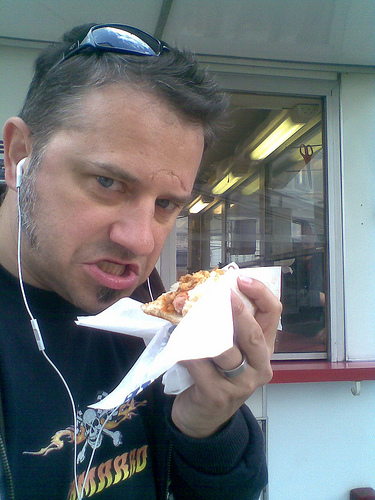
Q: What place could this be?
A: It is a shop.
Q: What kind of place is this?
A: It is a shop.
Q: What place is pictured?
A: It is a shop.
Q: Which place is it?
A: It is a shop.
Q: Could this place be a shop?
A: Yes, it is a shop.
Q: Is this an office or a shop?
A: It is a shop.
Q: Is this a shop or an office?
A: It is a shop.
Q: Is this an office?
A: No, it is a shop.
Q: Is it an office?
A: No, it is a shop.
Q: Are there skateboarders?
A: No, there are no skateboarders.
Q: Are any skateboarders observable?
A: No, there are no skateboarders.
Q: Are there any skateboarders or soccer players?
A: No, there are no skateboarders or soccer players.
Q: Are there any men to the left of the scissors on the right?
A: Yes, there is a man to the left of the scissors.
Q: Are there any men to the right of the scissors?
A: No, the man is to the left of the scissors.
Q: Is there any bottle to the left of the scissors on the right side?
A: No, there is a man to the left of the scissors.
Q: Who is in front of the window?
A: The man is in front of the window.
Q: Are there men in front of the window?
A: Yes, there is a man in front of the window.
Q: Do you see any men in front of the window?
A: Yes, there is a man in front of the window.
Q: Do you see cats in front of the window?
A: No, there is a man in front of the window.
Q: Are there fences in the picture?
A: No, there are no fences.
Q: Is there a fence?
A: No, there are no fences.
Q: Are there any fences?
A: No, there are no fences.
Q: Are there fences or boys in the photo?
A: No, there are no fences or boys.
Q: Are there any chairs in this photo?
A: No, there are no chairs.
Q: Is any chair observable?
A: No, there are no chairs.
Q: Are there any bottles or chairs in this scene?
A: No, there are no chairs or bottles.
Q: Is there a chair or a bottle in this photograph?
A: No, there are no chairs or bottles.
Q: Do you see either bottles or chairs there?
A: No, there are no chairs or bottles.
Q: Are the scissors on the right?
A: Yes, the scissors are on the right of the image.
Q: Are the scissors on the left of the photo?
A: No, the scissors are on the right of the image.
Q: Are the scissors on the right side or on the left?
A: The scissors are on the right of the image.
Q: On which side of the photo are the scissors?
A: The scissors are on the right of the image.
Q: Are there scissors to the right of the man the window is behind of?
A: Yes, there are scissors to the right of the man.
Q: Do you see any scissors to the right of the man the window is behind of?
A: Yes, there are scissors to the right of the man.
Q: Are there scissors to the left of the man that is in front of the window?
A: No, the scissors are to the right of the man.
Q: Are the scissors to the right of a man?
A: Yes, the scissors are to the right of a man.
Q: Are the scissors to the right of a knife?
A: No, the scissors are to the right of a man.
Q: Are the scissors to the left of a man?
A: No, the scissors are to the right of a man.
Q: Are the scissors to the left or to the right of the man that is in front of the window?
A: The scissors are to the right of the man.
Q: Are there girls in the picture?
A: No, there are no girls.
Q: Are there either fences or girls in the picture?
A: No, there are no girls or fences.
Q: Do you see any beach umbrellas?
A: No, there are no beach umbrellas.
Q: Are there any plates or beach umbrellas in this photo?
A: No, there are no beach umbrellas or plates.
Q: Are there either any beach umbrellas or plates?
A: No, there are no beach umbrellas or plates.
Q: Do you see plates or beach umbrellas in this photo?
A: No, there are no beach umbrellas or plates.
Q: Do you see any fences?
A: No, there are no fences.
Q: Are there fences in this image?
A: No, there are no fences.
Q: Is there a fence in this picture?
A: No, there are no fences.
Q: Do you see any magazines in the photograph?
A: No, there are no magazines.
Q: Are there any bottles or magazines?
A: No, there are no magazines or bottles.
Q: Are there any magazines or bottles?
A: No, there are no magazines or bottles.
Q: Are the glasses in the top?
A: Yes, the glasses are in the top of the image.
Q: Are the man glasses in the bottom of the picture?
A: No, the glasses are in the top of the image.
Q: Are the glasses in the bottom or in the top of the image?
A: The glasses are in the top of the image.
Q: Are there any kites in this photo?
A: No, there are no kites.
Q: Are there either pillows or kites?
A: No, there are no kites or pillows.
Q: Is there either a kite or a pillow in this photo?
A: No, there are no kites or pillows.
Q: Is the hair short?
A: Yes, the hair is short.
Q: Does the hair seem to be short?
A: Yes, the hair is short.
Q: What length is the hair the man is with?
A: The hair is short.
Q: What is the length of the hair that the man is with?
A: The hair is short.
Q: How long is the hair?
A: The hair is short.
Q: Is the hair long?
A: No, the hair is short.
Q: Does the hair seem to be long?
A: No, the hair is short.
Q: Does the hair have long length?
A: No, the hair is short.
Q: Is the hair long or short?
A: The hair is short.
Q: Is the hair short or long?
A: The hair is short.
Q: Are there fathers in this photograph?
A: No, there are no fathers.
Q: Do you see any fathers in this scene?
A: No, there are no fathers.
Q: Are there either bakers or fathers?
A: No, there are no fathers or bakers.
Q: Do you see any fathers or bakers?
A: No, there are no fathers or bakers.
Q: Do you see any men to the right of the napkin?
A: Yes, there is a man to the right of the napkin.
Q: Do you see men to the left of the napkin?
A: No, the man is to the right of the napkin.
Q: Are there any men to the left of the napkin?
A: No, the man is to the right of the napkin.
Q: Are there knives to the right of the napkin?
A: No, there is a man to the right of the napkin.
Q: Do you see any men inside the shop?
A: Yes, there is a man inside the shop.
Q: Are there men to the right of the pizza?
A: Yes, there is a man to the right of the pizza.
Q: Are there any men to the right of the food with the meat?
A: Yes, there is a man to the right of the pizza.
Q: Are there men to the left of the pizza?
A: No, the man is to the right of the pizza.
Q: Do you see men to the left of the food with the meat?
A: No, the man is to the right of the pizza.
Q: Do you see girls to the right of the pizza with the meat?
A: No, there is a man to the right of the pizza.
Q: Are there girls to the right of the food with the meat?
A: No, there is a man to the right of the pizza.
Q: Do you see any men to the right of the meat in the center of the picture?
A: Yes, there is a man to the right of the meat.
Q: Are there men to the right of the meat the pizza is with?
A: Yes, there is a man to the right of the meat.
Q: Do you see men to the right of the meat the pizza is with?
A: Yes, there is a man to the right of the meat.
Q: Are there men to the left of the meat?
A: No, the man is to the right of the meat.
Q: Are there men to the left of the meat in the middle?
A: No, the man is to the right of the meat.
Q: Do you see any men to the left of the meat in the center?
A: No, the man is to the right of the meat.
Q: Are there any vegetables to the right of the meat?
A: No, there is a man to the right of the meat.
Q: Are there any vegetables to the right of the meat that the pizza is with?
A: No, there is a man to the right of the meat.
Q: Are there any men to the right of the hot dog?
A: Yes, there is a man to the right of the hot dog.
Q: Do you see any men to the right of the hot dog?
A: Yes, there is a man to the right of the hot dog.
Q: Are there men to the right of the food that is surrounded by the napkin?
A: Yes, there is a man to the right of the hot dog.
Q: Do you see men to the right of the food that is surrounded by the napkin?
A: Yes, there is a man to the right of the hot dog.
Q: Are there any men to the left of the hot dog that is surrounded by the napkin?
A: No, the man is to the right of the hot dog.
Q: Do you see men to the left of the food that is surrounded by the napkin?
A: No, the man is to the right of the hot dog.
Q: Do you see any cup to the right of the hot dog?
A: No, there is a man to the right of the hot dog.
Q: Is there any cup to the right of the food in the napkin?
A: No, there is a man to the right of the hot dog.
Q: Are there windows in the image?
A: Yes, there is a window.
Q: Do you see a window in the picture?
A: Yes, there is a window.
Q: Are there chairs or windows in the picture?
A: Yes, there is a window.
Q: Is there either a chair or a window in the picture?
A: Yes, there is a window.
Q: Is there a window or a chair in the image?
A: Yes, there is a window.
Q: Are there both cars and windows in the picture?
A: No, there is a window but no cars.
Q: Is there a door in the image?
A: No, there are no doors.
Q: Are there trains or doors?
A: No, there are no doors or trains.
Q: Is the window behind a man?
A: Yes, the window is behind a man.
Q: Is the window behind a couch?
A: No, the window is behind a man.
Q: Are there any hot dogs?
A: Yes, there is a hot dog.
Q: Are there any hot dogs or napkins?
A: Yes, there is a hot dog.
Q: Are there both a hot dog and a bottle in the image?
A: No, there is a hot dog but no bottles.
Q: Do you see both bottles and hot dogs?
A: No, there is a hot dog but no bottles.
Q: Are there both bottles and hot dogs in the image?
A: No, there is a hot dog but no bottles.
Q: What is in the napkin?
A: The hot dog is in the napkin.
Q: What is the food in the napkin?
A: The food is a hot dog.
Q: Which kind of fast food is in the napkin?
A: The food is a hot dog.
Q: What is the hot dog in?
A: The hot dog is in the napkin.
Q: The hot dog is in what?
A: The hot dog is in the napkin.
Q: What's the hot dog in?
A: The hot dog is in the napkin.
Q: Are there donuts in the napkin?
A: No, there is a hot dog in the napkin.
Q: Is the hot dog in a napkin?
A: Yes, the hot dog is in a napkin.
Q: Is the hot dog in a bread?
A: No, the hot dog is in a napkin.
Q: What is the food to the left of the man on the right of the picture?
A: The food is a hot dog.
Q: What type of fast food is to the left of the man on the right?
A: The food is a hot dog.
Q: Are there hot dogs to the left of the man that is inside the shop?
A: Yes, there is a hot dog to the left of the man.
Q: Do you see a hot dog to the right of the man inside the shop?
A: No, the hot dog is to the left of the man.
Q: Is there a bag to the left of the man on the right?
A: No, there is a hot dog to the left of the man.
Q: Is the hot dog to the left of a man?
A: Yes, the hot dog is to the left of a man.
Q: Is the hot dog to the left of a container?
A: No, the hot dog is to the left of a man.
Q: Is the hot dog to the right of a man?
A: No, the hot dog is to the left of a man.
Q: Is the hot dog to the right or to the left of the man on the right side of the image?
A: The hot dog is to the left of the man.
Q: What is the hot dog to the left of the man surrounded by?
A: The hot dog is surrounded by the napkin.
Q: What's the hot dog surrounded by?
A: The hot dog is surrounded by the napkin.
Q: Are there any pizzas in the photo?
A: Yes, there is a pizza.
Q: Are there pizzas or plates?
A: Yes, there is a pizza.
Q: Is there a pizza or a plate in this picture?
A: Yes, there is a pizza.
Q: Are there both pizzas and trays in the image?
A: No, there is a pizza but no trays.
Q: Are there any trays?
A: No, there are no trays.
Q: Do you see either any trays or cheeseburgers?
A: No, there are no trays or cheeseburgers.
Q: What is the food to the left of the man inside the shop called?
A: The food is a pizza.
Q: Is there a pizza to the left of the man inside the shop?
A: Yes, there is a pizza to the left of the man.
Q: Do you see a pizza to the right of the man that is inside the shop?
A: No, the pizza is to the left of the man.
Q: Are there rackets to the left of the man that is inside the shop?
A: No, there is a pizza to the left of the man.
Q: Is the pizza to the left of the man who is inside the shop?
A: Yes, the pizza is to the left of the man.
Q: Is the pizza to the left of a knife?
A: No, the pizza is to the left of the man.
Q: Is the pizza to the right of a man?
A: No, the pizza is to the left of a man.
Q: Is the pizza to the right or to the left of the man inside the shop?
A: The pizza is to the left of the man.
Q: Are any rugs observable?
A: No, there are no rugs.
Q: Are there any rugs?
A: No, there are no rugs.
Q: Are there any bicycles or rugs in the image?
A: No, there are no rugs or bicycles.